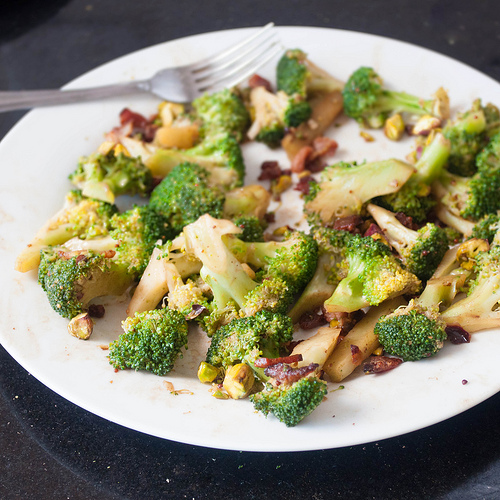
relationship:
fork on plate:
[2, 21, 286, 103] [2, 25, 500, 454]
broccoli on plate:
[15, 48, 496, 426] [2, 25, 500, 454]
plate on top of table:
[2, 25, 500, 454] [4, 2, 496, 499]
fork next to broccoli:
[2, 21, 286, 103] [15, 48, 496, 426]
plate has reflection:
[2, 25, 500, 454] [0, 364, 498, 500]